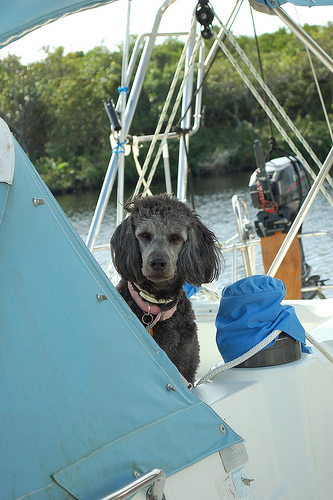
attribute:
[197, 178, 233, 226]
water — mirky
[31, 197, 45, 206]
attachment — small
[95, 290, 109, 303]
attachment — small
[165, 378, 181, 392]
attachment — small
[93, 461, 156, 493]
handle — silver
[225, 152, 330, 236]
motor — black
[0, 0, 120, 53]
awning — blue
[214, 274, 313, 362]
tarp — blue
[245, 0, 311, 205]
rope — black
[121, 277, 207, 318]
dog collar — pink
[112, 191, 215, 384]
dog — sitting, black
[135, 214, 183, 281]
hair — gray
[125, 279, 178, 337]
collar — red, yellow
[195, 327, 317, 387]
robe — white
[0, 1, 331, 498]
cover — blue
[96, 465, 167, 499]
hand railing — silver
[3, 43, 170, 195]
tree — green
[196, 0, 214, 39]
pulley — black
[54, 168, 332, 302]
water — tree lined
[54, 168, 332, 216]
shore — tree lined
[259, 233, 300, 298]
board — orange, wooden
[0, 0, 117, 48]
awning — blue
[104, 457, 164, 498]
railing — silver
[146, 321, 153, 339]
tag — orange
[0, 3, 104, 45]
trim — white